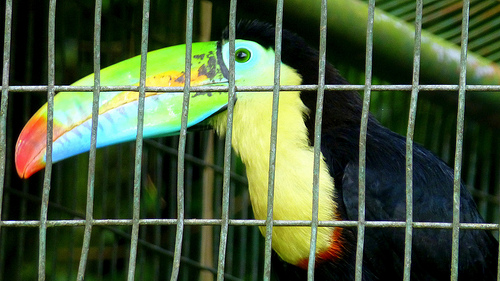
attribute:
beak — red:
[21, 58, 226, 172]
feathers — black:
[246, 21, 495, 279]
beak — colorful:
[7, 30, 245, 185]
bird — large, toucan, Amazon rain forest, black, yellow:
[13, 20, 497, 279]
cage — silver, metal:
[9, 4, 491, 265]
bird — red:
[21, 12, 498, 261]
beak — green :
[17, 37, 236, 170]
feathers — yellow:
[42, 46, 374, 228]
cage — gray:
[94, 24, 470, 274]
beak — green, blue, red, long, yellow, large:
[12, 42, 224, 182]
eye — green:
[216, 38, 264, 70]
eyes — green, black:
[233, 48, 248, 56]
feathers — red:
[217, 54, 495, 277]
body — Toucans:
[211, 21, 497, 277]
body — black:
[300, 63, 494, 280]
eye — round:
[233, 47, 253, 64]